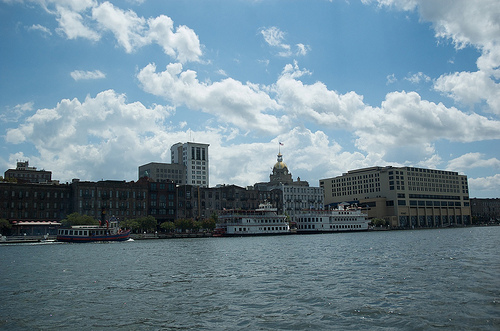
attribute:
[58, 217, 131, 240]
boat — red, white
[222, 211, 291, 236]
boat — large, white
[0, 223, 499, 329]
water — calm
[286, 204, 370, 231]
boat — large, white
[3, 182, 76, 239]
building — brown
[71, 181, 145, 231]
building — brown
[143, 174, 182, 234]
building — brown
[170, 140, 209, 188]
building — white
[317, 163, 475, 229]
building — beige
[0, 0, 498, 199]
clouds — white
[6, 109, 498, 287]
buildings — distant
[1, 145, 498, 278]
buildings — distant, in a set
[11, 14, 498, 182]
sky — cloudy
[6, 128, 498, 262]
buildings — distant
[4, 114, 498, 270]
buildings — distant, in a set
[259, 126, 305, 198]
dome — gold